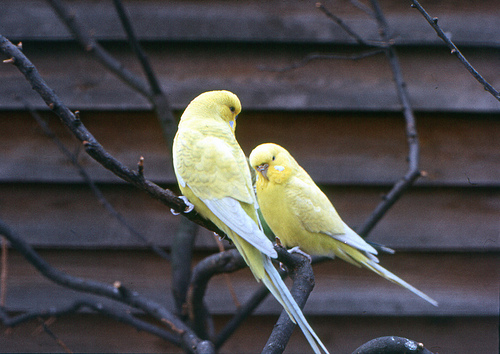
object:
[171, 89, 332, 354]
birds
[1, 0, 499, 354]
branch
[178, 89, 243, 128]
heads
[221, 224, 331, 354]
tails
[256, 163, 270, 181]
beaks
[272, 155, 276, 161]
eyes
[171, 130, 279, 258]
wings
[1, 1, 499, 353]
building